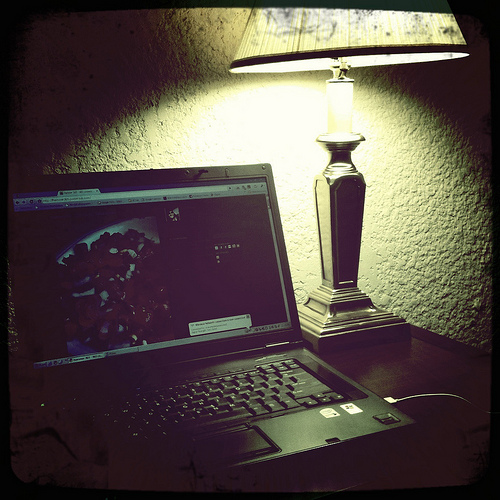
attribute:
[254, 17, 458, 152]
lamp — on, yellow, bright, brown, metal, lit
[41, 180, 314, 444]
laptop — on, black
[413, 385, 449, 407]
cord — white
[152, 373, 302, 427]
keyboard — black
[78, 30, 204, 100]
wall — white, lit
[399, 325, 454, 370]
table — brown